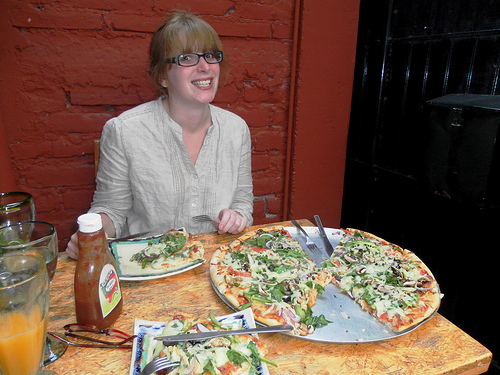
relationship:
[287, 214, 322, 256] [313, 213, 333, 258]
fork and a knife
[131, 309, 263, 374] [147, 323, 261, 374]
plate with pizza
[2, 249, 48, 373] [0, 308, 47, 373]
glass of orange juice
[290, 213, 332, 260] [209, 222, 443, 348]
fork and knife on pizza tray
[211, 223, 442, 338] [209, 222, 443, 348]
pizza on pizza tray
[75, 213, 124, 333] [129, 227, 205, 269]
bottle of sauce next to pizza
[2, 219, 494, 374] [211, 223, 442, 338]
table beneath pizza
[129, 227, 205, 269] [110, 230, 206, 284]
pizza half eaten on plate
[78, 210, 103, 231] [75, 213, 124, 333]
top on bottle of sauce